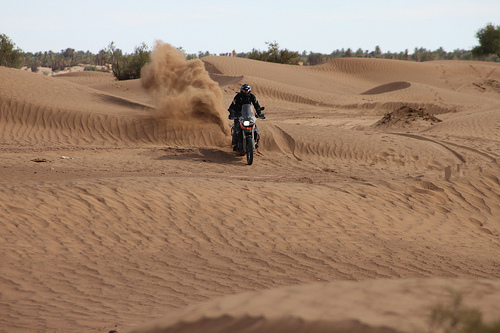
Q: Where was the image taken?
A: It was taken at the beach.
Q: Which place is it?
A: It is a beach.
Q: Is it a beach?
A: Yes, it is a beach.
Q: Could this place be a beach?
A: Yes, it is a beach.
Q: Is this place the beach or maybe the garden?
A: It is the beach.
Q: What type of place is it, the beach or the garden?
A: It is the beach.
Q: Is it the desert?
A: No, it is the beach.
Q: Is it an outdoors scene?
A: Yes, it is outdoors.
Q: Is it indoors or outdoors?
A: It is outdoors.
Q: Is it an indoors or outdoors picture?
A: It is outdoors.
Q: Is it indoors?
A: No, it is outdoors.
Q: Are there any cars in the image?
A: No, there are no cars.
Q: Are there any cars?
A: No, there are no cars.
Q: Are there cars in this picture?
A: No, there are no cars.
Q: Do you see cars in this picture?
A: No, there are no cars.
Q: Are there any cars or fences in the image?
A: No, there are no cars or fences.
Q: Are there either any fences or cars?
A: No, there are no fences or cars.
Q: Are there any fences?
A: No, there are no fences.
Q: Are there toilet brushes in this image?
A: No, there are no toilet brushes.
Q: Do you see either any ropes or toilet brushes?
A: No, there are no toilet brushes or ropes.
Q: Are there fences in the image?
A: No, there are no fences.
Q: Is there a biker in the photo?
A: Yes, there is a biker.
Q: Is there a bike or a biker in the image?
A: Yes, there is a biker.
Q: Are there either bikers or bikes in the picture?
A: Yes, there is a biker.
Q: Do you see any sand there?
A: Yes, there is sand.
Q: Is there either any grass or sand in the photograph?
A: Yes, there is sand.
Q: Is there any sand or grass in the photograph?
A: Yes, there is sand.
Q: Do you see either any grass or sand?
A: Yes, there is sand.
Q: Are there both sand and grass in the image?
A: No, there is sand but no grass.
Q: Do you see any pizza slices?
A: No, there are no pizza slices.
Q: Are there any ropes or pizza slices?
A: No, there are no pizza slices or ropes.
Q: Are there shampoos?
A: No, there are no shampoos.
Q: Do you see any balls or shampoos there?
A: No, there are no shampoos or balls.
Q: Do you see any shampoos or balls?
A: No, there are no shampoos or balls.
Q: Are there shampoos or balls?
A: No, there are no shampoos or balls.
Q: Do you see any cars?
A: No, there are no cars.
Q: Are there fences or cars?
A: No, there are no cars or fences.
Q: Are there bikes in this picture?
A: Yes, there is a bike.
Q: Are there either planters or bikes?
A: Yes, there is a bike.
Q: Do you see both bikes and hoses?
A: No, there is a bike but no hoses.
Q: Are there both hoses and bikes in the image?
A: No, there is a bike but no hoses.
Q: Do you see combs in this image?
A: No, there are no combs.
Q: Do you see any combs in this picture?
A: No, there are no combs.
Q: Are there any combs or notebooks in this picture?
A: No, there are no combs or notebooks.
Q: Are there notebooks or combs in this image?
A: No, there are no combs or notebooks.